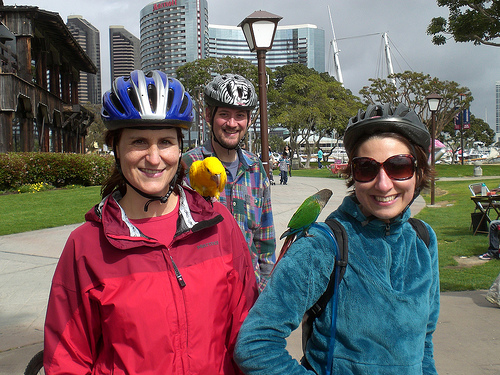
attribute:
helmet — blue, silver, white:
[91, 60, 202, 136]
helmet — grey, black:
[201, 68, 264, 128]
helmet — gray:
[337, 95, 434, 158]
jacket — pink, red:
[37, 184, 265, 374]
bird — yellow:
[183, 149, 235, 201]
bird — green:
[264, 185, 335, 272]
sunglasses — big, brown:
[348, 151, 421, 183]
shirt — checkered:
[182, 139, 279, 281]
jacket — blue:
[228, 205, 454, 374]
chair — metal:
[467, 175, 497, 233]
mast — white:
[379, 24, 405, 83]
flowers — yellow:
[14, 179, 57, 196]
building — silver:
[127, 1, 332, 86]